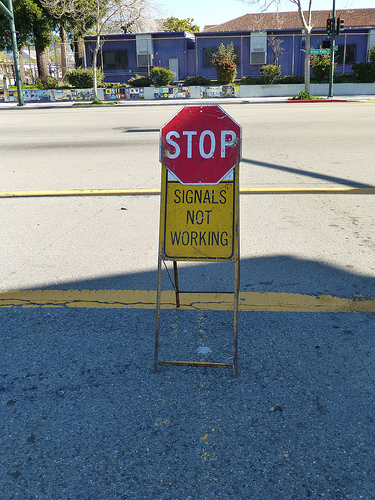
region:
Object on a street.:
[226, 371, 314, 467]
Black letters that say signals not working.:
[169, 180, 237, 258]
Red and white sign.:
[170, 94, 243, 171]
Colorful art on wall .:
[25, 73, 211, 104]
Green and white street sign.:
[294, 37, 352, 63]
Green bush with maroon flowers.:
[192, 40, 255, 95]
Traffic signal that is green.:
[314, 13, 343, 34]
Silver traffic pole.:
[10, 4, 21, 97]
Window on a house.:
[218, 22, 286, 91]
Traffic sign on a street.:
[54, 78, 319, 376]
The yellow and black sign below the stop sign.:
[162, 169, 237, 262]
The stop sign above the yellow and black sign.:
[158, 103, 244, 184]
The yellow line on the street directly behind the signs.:
[2, 289, 374, 313]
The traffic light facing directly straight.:
[327, 16, 334, 39]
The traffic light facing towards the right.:
[338, 15, 345, 36]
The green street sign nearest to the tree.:
[309, 46, 329, 55]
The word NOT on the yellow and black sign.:
[184, 203, 212, 224]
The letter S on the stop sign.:
[165, 128, 183, 157]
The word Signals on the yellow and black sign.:
[172, 186, 228, 205]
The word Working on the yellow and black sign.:
[170, 227, 228, 248]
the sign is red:
[152, 93, 255, 186]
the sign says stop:
[143, 95, 253, 181]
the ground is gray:
[92, 368, 212, 441]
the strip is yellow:
[255, 280, 349, 329]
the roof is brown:
[212, 0, 304, 49]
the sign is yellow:
[154, 151, 256, 286]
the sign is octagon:
[152, 66, 244, 203]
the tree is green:
[12, 1, 107, 40]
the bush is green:
[144, 51, 178, 96]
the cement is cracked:
[73, 274, 139, 334]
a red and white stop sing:
[142, 103, 252, 186]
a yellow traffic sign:
[136, 181, 238, 262]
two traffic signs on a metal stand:
[115, 101, 276, 497]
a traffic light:
[307, 14, 344, 55]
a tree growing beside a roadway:
[278, 3, 327, 221]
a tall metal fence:
[26, 33, 295, 78]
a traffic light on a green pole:
[2, 1, 25, 111]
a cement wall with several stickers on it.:
[1, 80, 354, 100]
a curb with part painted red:
[237, 92, 358, 111]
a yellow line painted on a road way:
[9, 256, 359, 339]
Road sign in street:
[149, 99, 244, 380]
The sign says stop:
[155, 102, 243, 186]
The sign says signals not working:
[157, 181, 240, 261]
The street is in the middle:
[1, 108, 372, 306]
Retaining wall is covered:
[4, 83, 374, 104]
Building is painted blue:
[83, 31, 373, 83]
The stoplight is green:
[323, 0, 346, 103]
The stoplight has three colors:
[1, 0, 26, 109]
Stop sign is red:
[157, 105, 244, 185]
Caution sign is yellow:
[152, 179, 239, 260]